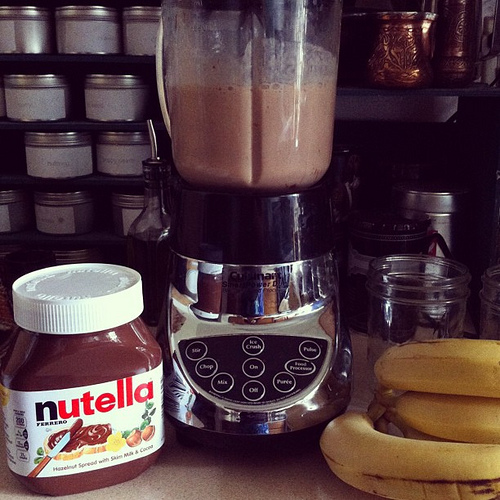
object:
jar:
[0, 264, 166, 496]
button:
[185, 341, 208, 362]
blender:
[155, 0, 353, 452]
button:
[211, 372, 235, 393]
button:
[242, 357, 265, 378]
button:
[273, 372, 296, 393]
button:
[299, 340, 321, 361]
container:
[55, 5, 123, 55]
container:
[84, 73, 150, 122]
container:
[3, 74, 72, 122]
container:
[24, 131, 93, 179]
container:
[96, 131, 152, 178]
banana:
[373, 339, 500, 399]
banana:
[375, 390, 500, 443]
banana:
[319, 403, 500, 500]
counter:
[0, 263, 500, 500]